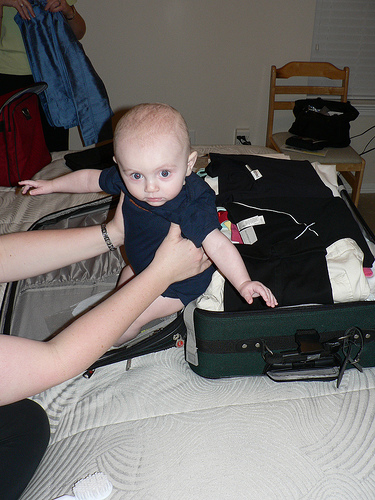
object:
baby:
[17, 100, 278, 352]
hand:
[239, 280, 278, 309]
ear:
[112, 154, 118, 164]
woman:
[0, 188, 213, 464]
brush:
[52, 470, 114, 500]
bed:
[0, 143, 374, 498]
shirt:
[98, 164, 224, 309]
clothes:
[205, 150, 375, 312]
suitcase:
[0, 151, 375, 389]